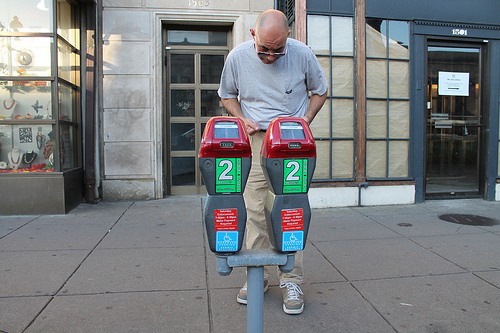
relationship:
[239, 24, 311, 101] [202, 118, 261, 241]
man looking at meter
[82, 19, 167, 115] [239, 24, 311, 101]
building behind man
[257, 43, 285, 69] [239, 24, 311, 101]
glasses on man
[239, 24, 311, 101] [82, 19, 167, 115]
man near building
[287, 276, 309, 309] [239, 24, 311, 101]
shoes on man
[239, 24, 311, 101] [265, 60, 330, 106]
man in shirt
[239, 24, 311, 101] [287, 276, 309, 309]
man in shoes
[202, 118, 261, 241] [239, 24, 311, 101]
meter near man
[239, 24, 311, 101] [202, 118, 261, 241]
man near meter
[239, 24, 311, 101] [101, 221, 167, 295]
man on sidewalk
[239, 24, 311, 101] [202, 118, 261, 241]
man watching meter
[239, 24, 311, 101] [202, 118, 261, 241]
man on meter